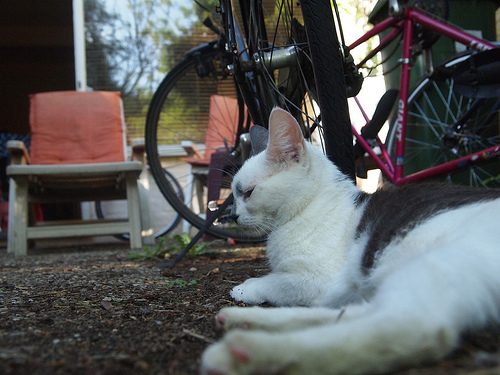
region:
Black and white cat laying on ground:
[199, 126, 497, 366]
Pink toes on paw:
[192, 323, 249, 373]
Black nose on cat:
[222, 177, 259, 236]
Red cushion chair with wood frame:
[8, 63, 229, 265]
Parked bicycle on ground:
[143, 0, 486, 202]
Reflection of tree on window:
[90, 8, 164, 104]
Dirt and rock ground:
[19, 248, 190, 362]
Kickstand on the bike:
[136, 179, 277, 269]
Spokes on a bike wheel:
[223, 11, 378, 133]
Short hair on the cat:
[282, 196, 376, 274]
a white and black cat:
[196, 94, 497, 369]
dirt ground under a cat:
[4, 247, 498, 365]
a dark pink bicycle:
[139, 6, 494, 212]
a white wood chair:
[4, 78, 145, 265]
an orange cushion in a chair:
[22, 85, 137, 165]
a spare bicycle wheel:
[93, 155, 199, 245]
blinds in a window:
[84, 4, 302, 145]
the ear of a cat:
[261, 102, 308, 163]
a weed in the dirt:
[169, 229, 228, 262]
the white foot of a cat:
[213, 301, 401, 330]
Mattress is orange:
[27, 87, 124, 167]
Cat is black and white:
[195, 102, 497, 374]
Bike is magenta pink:
[140, 0, 496, 271]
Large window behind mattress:
[80, 0, 321, 152]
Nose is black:
[228, 207, 238, 222]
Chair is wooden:
[0, 90, 155, 250]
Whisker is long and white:
[257, 212, 304, 250]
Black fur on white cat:
[346, 180, 493, 275]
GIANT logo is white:
[393, 95, 403, 142]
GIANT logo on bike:
[392, 92, 403, 143]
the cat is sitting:
[204, 99, 470, 367]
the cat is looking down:
[138, 70, 357, 259]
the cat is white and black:
[214, 127, 479, 351]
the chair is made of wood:
[16, 87, 176, 280]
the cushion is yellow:
[32, 80, 123, 173]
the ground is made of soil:
[43, 257, 174, 360]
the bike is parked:
[135, 26, 462, 217]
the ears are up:
[210, 100, 363, 215]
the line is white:
[18, 22, 127, 103]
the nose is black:
[209, 177, 259, 239]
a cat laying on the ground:
[201, 101, 496, 371]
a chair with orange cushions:
[3, 87, 145, 258]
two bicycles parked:
[131, 0, 497, 270]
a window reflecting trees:
[80, 3, 305, 145]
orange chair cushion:
[26, 88, 121, 161]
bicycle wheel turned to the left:
[140, 43, 265, 239]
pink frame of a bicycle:
[350, 6, 495, 184]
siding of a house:
[1, 1, 71, 91]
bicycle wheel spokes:
[407, 77, 464, 152]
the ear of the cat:
[265, 104, 307, 174]